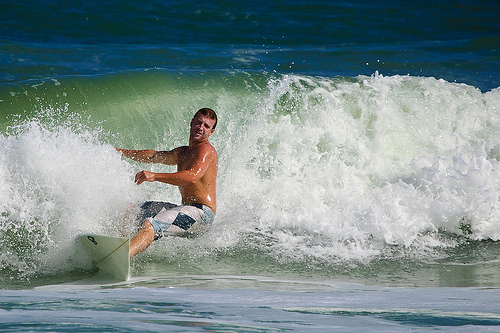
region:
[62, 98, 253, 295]
man on a surfboard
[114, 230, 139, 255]
tip of the surfboard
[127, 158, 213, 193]
arm is bent at the elbow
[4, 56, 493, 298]
man surfing a wave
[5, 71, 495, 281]
wave in the water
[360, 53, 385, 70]
two drops of water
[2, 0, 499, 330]
body of water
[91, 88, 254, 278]
man is leaning back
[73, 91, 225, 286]
man surfing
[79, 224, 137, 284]
white surfboard coming out of the water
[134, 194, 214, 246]
board shorts the surfer is wearing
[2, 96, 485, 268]
white spray from the wave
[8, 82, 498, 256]
wave the surfer is riding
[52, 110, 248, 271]
surfer riding white surfboard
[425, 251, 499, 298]
reflection on the water's surface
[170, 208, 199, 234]
navy blue diamon shape on the board shorts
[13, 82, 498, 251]
wave crashing back in to the ocean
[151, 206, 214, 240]
light blue triangle shapes on the board shorts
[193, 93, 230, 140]
Man has short hair.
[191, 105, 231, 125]
Man has brown hair.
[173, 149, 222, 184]
Man is bare chested.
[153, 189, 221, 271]
Man is wearing shorts.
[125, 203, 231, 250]
Man's shorts are blue and white.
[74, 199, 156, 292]
Man is standing on surfboard.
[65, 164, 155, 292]
Man's surfboard is white in color.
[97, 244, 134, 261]
Gold stripe on bottom of board.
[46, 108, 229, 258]
Man surfing in water.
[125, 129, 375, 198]
Top of water on wave is white.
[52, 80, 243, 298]
a surfer in front a wave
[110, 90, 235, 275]
the surfer bend backward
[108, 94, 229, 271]
surfer wears blue and gray short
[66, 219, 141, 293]
the surfboard is color white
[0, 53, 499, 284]
the wave is big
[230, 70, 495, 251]
the foam of a wave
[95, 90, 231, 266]
man has hands in front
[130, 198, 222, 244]
short is blue and gray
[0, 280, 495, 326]
the water is calm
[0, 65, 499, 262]
the water is choppy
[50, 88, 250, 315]
the man is surfing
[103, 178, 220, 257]
the man is wearing shorts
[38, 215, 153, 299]
the surfboard is white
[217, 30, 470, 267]
the waves are white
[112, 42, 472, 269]
the wave is rolling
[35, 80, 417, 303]
the wave is splashing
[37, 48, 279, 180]
the water is green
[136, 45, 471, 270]
the water is in motion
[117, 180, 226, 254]
the shorts are blue and white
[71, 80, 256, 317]
the man is leaning to the right